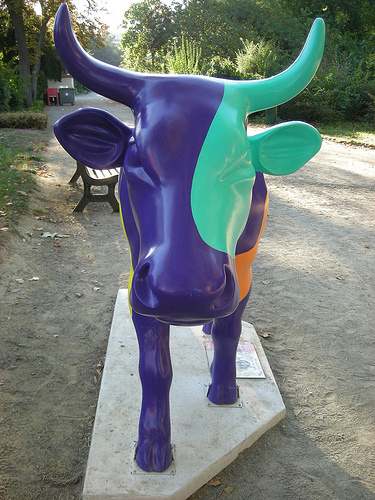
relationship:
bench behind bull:
[69, 161, 120, 214] [51, 1, 326, 473]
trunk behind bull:
[9, 10, 34, 109] [51, 1, 326, 473]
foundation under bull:
[81, 287, 287, 499] [51, 1, 326, 473]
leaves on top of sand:
[1, 169, 71, 253] [2, 102, 374, 500]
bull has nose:
[51, 1, 326, 473] [128, 261, 238, 321]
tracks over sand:
[268, 229, 373, 304] [2, 102, 374, 500]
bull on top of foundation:
[51, 1, 326, 473] [81, 287, 287, 499]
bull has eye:
[51, 1, 326, 473] [125, 144, 146, 175]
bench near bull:
[69, 161, 120, 214] [51, 1, 326, 473]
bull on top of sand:
[51, 1, 326, 473] [2, 102, 374, 500]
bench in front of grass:
[69, 161, 120, 214] [0, 142, 45, 251]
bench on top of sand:
[69, 161, 120, 214] [2, 102, 374, 500]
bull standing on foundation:
[51, 1, 326, 473] [81, 287, 287, 499]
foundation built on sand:
[81, 287, 287, 499] [2, 102, 374, 500]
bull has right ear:
[51, 1, 326, 473] [52, 107, 127, 172]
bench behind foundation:
[69, 161, 120, 214] [81, 287, 287, 499]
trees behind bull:
[120, 1, 374, 119] [51, 1, 326, 473]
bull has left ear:
[51, 1, 326, 473] [250, 118, 322, 176]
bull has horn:
[52, 1, 325, 472] [244, 16, 328, 118]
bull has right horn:
[52, 1, 325, 472] [53, 2, 132, 110]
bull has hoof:
[52, 1, 325, 472] [133, 439, 173, 474]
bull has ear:
[52, 1, 325, 472] [52, 105, 130, 173]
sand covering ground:
[2, 102, 374, 500] [3, 92, 374, 496]